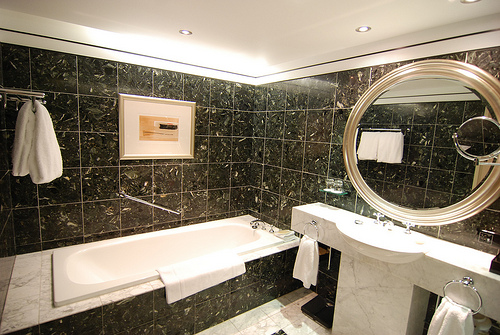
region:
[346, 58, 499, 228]
a round mirror on the wall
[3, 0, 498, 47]
the ceiling of the bathroom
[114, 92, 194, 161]
a painting on the wall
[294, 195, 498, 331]
a counter with a sink in it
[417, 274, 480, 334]
a towel hanging on a ring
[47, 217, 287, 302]
a white bathtub in the corner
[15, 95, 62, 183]
a towel hanging from a pole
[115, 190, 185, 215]
a pole hanging from the wall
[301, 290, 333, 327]
the scale on the floor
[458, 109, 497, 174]
a tiny mirror by the big mirror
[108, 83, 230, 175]
Picture in a silver colored frame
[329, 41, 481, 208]
Mirror in silver frame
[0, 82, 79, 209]
White towel hanging from silver colored hanger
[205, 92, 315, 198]
Marble colored tile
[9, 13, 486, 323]
A bathroom with silver and white colored fixtures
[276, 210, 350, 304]
Towel hanging from white sink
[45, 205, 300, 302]
A bath tub with a towel hanging from one side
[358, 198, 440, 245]
A facet on the sink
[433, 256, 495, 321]
A silver colored towel hanger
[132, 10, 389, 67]
Recessed lighting in bathroom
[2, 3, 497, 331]
a large bathroom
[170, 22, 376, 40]
recessed lighting in the ceiling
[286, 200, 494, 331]
marble counter-top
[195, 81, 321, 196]
large dark tiles on the wall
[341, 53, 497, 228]
large oval mirror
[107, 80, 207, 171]
framed and matted object on wall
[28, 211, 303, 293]
large tub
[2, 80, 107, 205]
white towel hanging near wall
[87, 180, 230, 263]
slanted rail above tub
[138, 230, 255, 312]
white towel hanging over edge of tub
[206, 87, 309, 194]
black tile on the walls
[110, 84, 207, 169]
a picture in a silver frame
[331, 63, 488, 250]
the mirror is large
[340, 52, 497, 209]
the mirror has a silver rim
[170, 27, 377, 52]
recessed lights in the ceiling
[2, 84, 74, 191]
a towel hanging from a rack on the wall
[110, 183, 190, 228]
a safety handle to get out of the tub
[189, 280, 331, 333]
a white tile floor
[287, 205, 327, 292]
towel hanging from a ring at the sink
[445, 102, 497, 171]
small mirror that swivels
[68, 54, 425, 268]
bathroom with black tiles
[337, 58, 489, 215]
round mirror in bathroom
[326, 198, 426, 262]
white sink with two knobs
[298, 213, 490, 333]
two towels hanging from sink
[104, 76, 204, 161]
picture on wall above bathtub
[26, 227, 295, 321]
white bathtub in tiles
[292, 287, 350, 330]
scale for measuring weight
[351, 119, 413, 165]
reflection of white towels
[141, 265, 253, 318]
white towel on tub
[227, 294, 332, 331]
white tile bathroom floor